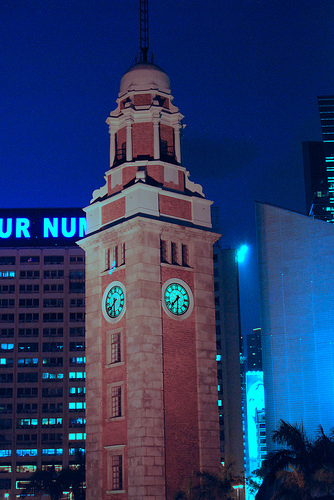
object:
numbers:
[183, 291, 186, 297]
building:
[0, 206, 92, 497]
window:
[111, 329, 123, 363]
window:
[105, 383, 119, 417]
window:
[109, 453, 123, 493]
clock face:
[100, 280, 126, 323]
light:
[1, 269, 16, 277]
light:
[0, 342, 11, 349]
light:
[19, 419, 64, 423]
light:
[42, 371, 64, 381]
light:
[66, 431, 86, 441]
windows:
[1, 272, 7, 279]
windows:
[40, 316, 47, 324]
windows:
[56, 373, 62, 380]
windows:
[16, 388, 22, 400]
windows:
[44, 271, 51, 277]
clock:
[164, 276, 190, 318]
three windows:
[102, 241, 130, 275]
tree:
[256, 413, 333, 491]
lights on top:
[14, 214, 31, 239]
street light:
[232, 244, 247, 260]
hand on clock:
[164, 293, 184, 310]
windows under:
[64, 428, 74, 446]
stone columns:
[152, 113, 160, 158]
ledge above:
[137, 212, 225, 238]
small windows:
[156, 243, 163, 265]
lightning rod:
[126, 3, 158, 51]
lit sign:
[0, 218, 87, 239]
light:
[214, 353, 221, 363]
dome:
[111, 61, 184, 109]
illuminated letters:
[40, 214, 61, 241]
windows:
[78, 251, 84, 262]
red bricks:
[150, 348, 157, 361]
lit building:
[295, 97, 333, 219]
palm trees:
[310, 425, 325, 487]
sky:
[4, 8, 316, 216]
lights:
[57, 371, 62, 381]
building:
[81, 64, 219, 497]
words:
[60, 216, 73, 236]